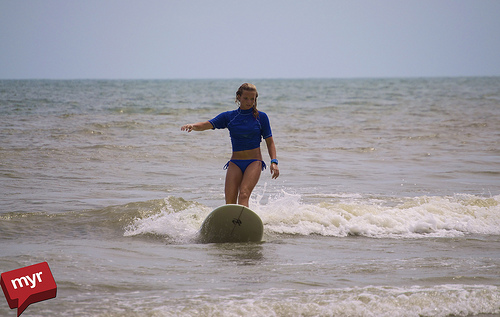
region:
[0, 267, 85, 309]
the letters MYR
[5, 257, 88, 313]
MYR box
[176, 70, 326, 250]
a women surfer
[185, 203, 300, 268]
a white surfboard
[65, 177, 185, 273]
waves in the water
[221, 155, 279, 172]
the bikini bottom of the surfer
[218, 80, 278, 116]
the face of the surger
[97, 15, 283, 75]
the clear sky in the background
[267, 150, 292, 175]
something on the wrist of the surfer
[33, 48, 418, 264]
a cool surf scene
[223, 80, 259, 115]
the head of the woman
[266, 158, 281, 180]
the hand of the woman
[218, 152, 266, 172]
the bikini bottom of the woman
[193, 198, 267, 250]
a white surfboard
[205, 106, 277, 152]
a blue shirt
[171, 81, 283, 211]
a woman on the surfboard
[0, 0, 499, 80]
a clear blue sky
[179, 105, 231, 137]
the arm of the woman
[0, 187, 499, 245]
a small wave in the water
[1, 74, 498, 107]
calm blue ocean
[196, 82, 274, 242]
Woman surfing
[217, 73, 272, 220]
Woman in blue top surfing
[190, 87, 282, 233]
Woman in blue bottoms surfing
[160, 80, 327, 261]
Woman in blue bikini bottom surfing.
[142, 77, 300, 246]
Woman in blue surfing on top of white surfboard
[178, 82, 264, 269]
Woman in blue bikini bottom surfing on surfboard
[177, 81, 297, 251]
Woman in blue bikini bottom surfing on top of white surfboard in ocean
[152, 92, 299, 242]
Woman wearing blue bracelet surfing.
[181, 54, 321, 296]
Woman standing on top of surfboard.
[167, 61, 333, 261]
White surfboard with woman standing on top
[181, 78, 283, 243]
Girl is standing on surfboard.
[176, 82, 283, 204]
Girl has well formed tan.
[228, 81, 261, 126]
Girls hair is wet.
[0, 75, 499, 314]
Ocean water is ripply.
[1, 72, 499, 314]
Water is very wavy.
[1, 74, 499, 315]
Water in horizon is bluer.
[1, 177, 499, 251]
The wave has settled.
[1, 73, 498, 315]
Ocean water is pretty even-tempered.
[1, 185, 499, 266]
The wave is very mild.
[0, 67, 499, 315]
There's no other people with the girl.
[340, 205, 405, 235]
small white wave in water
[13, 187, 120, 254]
gray wave in the water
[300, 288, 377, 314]
small bubbles at edge of water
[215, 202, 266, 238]
small string at bottom of surf board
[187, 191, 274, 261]
round edge of surfboard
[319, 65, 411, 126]
calm seas in the background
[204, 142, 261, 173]
strings on woman's blue bikini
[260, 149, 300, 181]
blue wrist band on hand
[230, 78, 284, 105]
blond hair on woman's head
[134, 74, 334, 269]
woman balancing on surf board